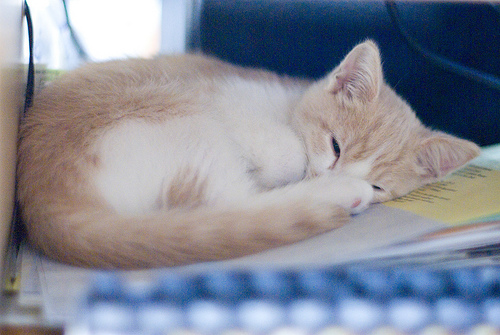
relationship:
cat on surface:
[17, 37, 485, 272] [281, 179, 468, 316]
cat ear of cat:
[326, 37, 381, 104] [36, 29, 458, 289]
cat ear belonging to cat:
[326, 37, 381, 104] [17, 37, 485, 272]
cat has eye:
[17, 37, 485, 272] [321, 128, 342, 155]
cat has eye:
[17, 37, 485, 272] [368, 179, 387, 201]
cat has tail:
[17, 37, 485, 272] [58, 175, 372, 267]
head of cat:
[298, 44, 473, 184] [17, 37, 485, 272]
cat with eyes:
[17, 36, 478, 266] [332, 127, 386, 207]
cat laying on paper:
[17, 36, 478, 266] [1, 136, 499, 318]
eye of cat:
[322, 118, 345, 162] [17, 36, 478, 266]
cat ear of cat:
[326, 37, 381, 104] [17, 36, 478, 266]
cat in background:
[17, 36, 478, 266] [25, 9, 482, 141]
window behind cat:
[60, 6, 188, 70] [17, 36, 478, 266]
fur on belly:
[176, 145, 305, 195] [131, 107, 281, 213]